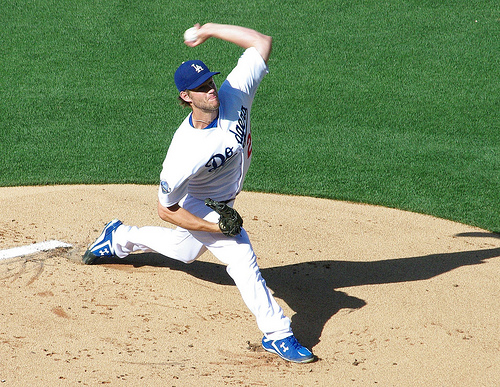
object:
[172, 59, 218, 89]
hat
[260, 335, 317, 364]
shoe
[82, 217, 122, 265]
shoe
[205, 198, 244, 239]
glove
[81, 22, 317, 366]
man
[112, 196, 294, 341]
pants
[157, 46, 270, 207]
shirt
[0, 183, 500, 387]
base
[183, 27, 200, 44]
ball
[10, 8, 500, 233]
grass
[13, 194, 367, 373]
sand